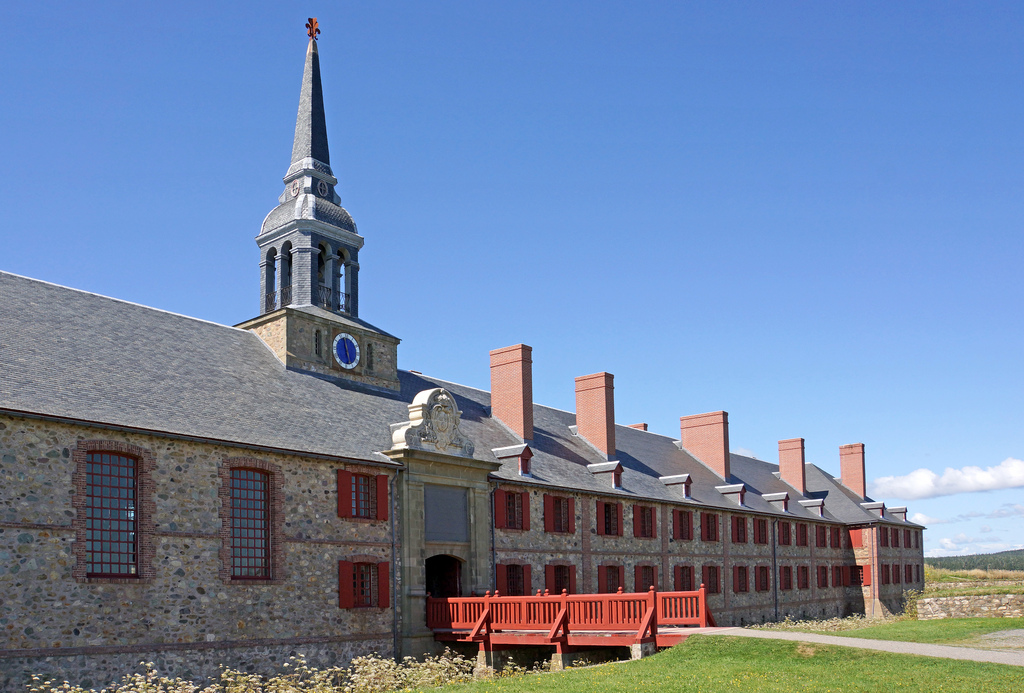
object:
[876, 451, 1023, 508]
clouds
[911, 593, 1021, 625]
wall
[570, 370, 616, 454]
chimney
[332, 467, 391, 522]
window fram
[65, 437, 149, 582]
window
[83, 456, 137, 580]
safety bars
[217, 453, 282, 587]
frame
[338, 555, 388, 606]
frame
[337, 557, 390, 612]
window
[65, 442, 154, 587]
frame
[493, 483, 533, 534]
window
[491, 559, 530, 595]
window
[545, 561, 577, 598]
window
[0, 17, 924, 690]
church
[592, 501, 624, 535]
window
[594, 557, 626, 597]
window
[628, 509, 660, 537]
window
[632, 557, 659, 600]
window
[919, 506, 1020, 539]
clouds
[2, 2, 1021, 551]
sky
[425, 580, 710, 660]
bridge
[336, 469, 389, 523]
window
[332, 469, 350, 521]
shutter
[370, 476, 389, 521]
shutter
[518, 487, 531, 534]
shutters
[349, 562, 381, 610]
window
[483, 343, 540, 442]
chimney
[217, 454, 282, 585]
windows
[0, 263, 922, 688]
building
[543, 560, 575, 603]
window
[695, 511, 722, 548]
window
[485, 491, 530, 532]
window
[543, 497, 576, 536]
window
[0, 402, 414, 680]
wall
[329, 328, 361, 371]
clock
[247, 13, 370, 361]
tower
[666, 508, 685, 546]
shutters